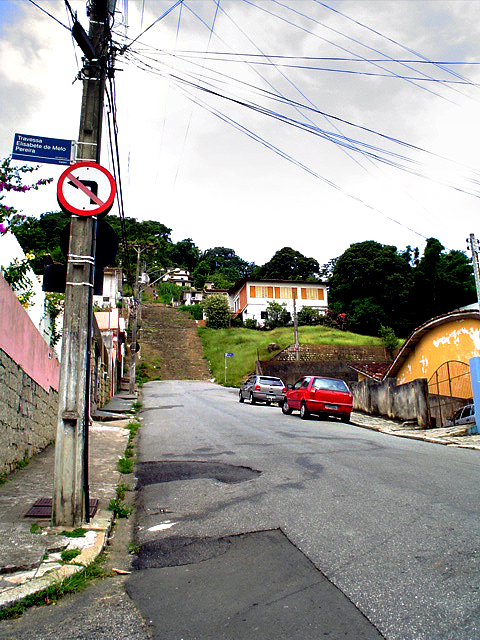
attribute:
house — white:
[209, 207, 462, 451]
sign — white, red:
[61, 159, 115, 212]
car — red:
[270, 265, 375, 409]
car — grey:
[223, 352, 305, 420]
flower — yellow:
[9, 233, 68, 272]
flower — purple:
[3, 148, 30, 203]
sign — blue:
[5, 104, 87, 181]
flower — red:
[326, 292, 362, 338]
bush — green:
[162, 251, 299, 358]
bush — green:
[200, 275, 291, 342]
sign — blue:
[13, 110, 103, 232]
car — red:
[221, 341, 364, 446]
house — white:
[215, 244, 397, 446]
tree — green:
[270, 239, 316, 293]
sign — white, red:
[38, 156, 123, 217]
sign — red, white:
[41, 139, 120, 228]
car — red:
[285, 365, 418, 468]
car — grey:
[180, 335, 285, 396]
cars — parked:
[226, 327, 372, 494]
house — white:
[237, 253, 407, 434]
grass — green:
[250, 312, 312, 379]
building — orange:
[393, 278, 463, 415]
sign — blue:
[15, 97, 72, 176]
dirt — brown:
[164, 286, 218, 383]